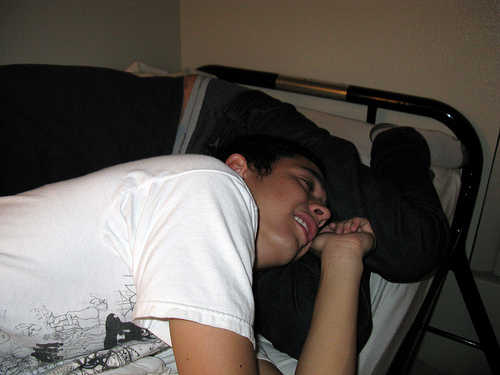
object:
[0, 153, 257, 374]
white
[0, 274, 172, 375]
drawing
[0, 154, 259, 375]
boy's shirt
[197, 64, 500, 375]
bar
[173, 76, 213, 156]
elastic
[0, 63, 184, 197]
sweatshirt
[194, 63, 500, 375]
metal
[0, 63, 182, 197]
blackshirt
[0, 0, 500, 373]
wall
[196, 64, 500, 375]
metal frame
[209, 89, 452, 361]
sweatshirt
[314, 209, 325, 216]
nostril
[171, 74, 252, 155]
gray underwear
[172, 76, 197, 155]
border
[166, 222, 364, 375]
arm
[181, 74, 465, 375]
headboard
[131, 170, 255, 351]
sleeve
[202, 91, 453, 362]
pants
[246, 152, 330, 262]
mouth face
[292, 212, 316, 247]
mouth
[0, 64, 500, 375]
bed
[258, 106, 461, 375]
sheet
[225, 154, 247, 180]
ear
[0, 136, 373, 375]
boy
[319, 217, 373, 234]
finger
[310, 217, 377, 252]
hand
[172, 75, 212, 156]
elastic band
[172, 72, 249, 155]
boy's underwear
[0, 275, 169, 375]
design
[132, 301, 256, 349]
edge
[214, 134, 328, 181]
hair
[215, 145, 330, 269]
head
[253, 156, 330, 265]
face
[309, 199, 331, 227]
nose